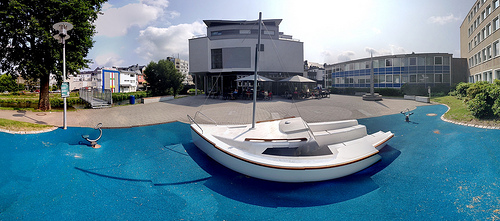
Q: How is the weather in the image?
A: It is sunny.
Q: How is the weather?
A: It is sunny.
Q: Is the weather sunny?
A: Yes, it is sunny.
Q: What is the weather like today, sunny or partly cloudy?
A: It is sunny.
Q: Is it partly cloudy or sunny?
A: It is sunny.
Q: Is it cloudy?
A: No, it is sunny.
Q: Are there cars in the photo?
A: No, there are no cars.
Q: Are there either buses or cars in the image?
A: No, there are no cars or buses.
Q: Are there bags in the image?
A: No, there are no bags.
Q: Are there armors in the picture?
A: No, there are no armors.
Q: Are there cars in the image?
A: No, there are no cars.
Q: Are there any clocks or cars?
A: No, there are no cars or clocks.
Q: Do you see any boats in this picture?
A: Yes, there is a boat.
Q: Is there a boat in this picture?
A: Yes, there is a boat.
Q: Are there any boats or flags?
A: Yes, there is a boat.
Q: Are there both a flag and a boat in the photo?
A: No, there is a boat but no flags.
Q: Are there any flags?
A: No, there are no flags.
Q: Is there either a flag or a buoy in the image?
A: No, there are no flags or buoys.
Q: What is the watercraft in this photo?
A: The watercraft is a boat.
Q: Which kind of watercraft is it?
A: The watercraft is a boat.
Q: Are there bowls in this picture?
A: No, there are no bowls.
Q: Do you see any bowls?
A: No, there are no bowls.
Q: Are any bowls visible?
A: No, there are no bowls.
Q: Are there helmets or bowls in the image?
A: No, there are no bowls or helmets.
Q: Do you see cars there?
A: No, there are no cars.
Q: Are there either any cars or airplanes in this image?
A: No, there are no cars or airplanes.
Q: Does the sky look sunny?
A: Yes, the sky is sunny.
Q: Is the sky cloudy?
A: No, the sky is sunny.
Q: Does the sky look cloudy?
A: No, the sky is sunny.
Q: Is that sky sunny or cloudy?
A: The sky is sunny.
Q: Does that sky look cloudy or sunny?
A: The sky is sunny.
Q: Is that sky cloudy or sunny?
A: The sky is sunny.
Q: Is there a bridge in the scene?
A: Yes, there is a bridge.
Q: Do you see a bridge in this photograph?
A: Yes, there is a bridge.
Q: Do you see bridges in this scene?
A: Yes, there is a bridge.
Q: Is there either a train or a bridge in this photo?
A: Yes, there is a bridge.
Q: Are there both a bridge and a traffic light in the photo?
A: No, there is a bridge but no traffic lights.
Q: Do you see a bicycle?
A: No, there are no bicycles.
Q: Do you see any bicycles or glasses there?
A: No, there are no bicycles or glasses.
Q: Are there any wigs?
A: No, there are no wigs.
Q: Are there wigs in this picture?
A: No, there are no wigs.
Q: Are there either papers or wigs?
A: No, there are no wigs or papers.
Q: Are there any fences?
A: Yes, there is a fence.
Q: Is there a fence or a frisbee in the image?
A: Yes, there is a fence.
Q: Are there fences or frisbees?
A: Yes, there is a fence.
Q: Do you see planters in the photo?
A: No, there are no planters.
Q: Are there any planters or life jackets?
A: No, there are no planters or life jackets.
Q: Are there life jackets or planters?
A: No, there are no planters or life jackets.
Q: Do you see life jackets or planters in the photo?
A: No, there are no planters or life jackets.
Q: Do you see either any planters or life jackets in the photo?
A: No, there are no planters or life jackets.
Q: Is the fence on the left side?
A: Yes, the fence is on the left of the image.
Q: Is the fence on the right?
A: No, the fence is on the left of the image.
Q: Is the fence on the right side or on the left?
A: The fence is on the left of the image.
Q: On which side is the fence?
A: The fence is on the left of the image.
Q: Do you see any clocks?
A: No, there are no clocks.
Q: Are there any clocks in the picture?
A: No, there are no clocks.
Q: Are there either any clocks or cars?
A: No, there are no clocks or cars.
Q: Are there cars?
A: No, there are no cars.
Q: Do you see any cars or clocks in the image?
A: No, there are no cars or clocks.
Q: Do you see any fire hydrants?
A: No, there are no fire hydrants.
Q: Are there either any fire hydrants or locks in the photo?
A: No, there are no fire hydrants or locks.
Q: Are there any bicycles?
A: No, there are no bicycles.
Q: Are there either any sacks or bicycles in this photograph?
A: No, there are no bicycles or sacks.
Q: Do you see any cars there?
A: No, there are no cars.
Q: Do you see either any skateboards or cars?
A: No, there are no cars or skateboards.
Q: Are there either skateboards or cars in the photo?
A: No, there are no cars or skateboards.